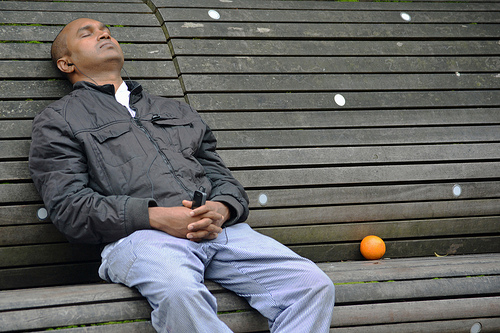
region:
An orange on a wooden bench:
[348, 225, 408, 268]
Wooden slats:
[278, 21, 480, 216]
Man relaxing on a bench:
[35, 13, 338, 321]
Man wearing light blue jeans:
[28, 171, 347, 328]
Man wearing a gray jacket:
[26, 80, 280, 237]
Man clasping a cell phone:
[141, 180, 263, 247]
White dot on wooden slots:
[302, 68, 392, 133]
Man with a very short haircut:
[41, 11, 167, 93]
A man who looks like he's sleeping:
[42, 14, 159, 84]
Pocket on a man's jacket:
[76, 110, 166, 175]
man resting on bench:
[39, 11, 309, 304]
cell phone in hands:
[184, 179, 216, 221]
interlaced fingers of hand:
[181, 206, 227, 245]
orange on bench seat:
[349, 227, 389, 269]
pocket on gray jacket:
[90, 119, 144, 181]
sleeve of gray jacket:
[50, 179, 147, 234]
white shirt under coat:
[109, 72, 141, 132]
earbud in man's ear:
[61, 57, 92, 83]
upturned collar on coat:
[70, 78, 124, 107]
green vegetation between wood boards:
[7, 17, 47, 58]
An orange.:
[353, 230, 397, 267]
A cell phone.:
[176, 185, 226, 224]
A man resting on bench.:
[26, 17, 350, 330]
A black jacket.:
[23, 79, 307, 234]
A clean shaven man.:
[41, 10, 176, 109]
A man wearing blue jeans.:
[22, 10, 357, 331]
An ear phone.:
[25, 45, 117, 102]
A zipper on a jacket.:
[126, 115, 211, 211]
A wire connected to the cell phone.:
[183, 184, 240, 248]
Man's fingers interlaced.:
[138, 197, 255, 242]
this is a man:
[20, 0, 243, 321]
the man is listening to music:
[52, 0, 130, 100]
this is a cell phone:
[188, 185, 209, 207]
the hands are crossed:
[177, 205, 226, 239]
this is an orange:
[359, 234, 385, 259]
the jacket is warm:
[57, 117, 177, 181]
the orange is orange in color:
[357, 234, 384, 260]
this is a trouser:
[161, 245, 276, 330]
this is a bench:
[267, 29, 458, 183]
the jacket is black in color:
[94, 124, 182, 184]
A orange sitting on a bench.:
[348, 210, 401, 260]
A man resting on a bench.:
[35, 10, 336, 327]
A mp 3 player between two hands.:
[176, 190, 216, 255]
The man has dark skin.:
[165, 205, 175, 220]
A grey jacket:
[122, 118, 185, 179]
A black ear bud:
[66, 61, 87, 82]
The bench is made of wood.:
[233, 31, 381, 151]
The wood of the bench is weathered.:
[303, 44, 430, 147]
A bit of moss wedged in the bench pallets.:
[14, 19, 48, 29]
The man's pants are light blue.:
[139, 235, 180, 287]